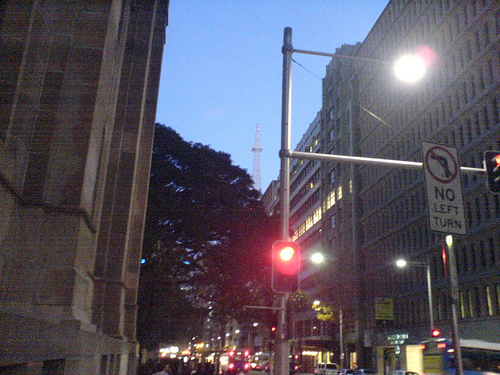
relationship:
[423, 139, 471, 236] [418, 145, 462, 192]
sign with circle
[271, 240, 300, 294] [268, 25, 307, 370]
light on pole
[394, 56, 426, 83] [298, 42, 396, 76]
light on pole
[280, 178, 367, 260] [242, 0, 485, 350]
lights on building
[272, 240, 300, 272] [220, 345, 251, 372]
red light on car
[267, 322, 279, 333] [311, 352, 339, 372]
red light on car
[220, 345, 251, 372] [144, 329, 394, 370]
car on street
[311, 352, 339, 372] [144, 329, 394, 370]
car on street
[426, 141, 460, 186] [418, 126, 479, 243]
circle around arrow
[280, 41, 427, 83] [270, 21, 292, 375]
horizontal pole on pole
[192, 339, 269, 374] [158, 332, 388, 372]
traffic on city street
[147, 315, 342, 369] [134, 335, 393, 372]
lights over street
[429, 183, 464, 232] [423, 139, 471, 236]
words on sign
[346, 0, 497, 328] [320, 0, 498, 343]
face of building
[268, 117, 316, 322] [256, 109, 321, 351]
face of building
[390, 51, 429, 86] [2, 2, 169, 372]
light near building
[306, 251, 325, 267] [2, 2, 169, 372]
light near building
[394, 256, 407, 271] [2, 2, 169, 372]
light near building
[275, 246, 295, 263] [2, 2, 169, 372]
light near building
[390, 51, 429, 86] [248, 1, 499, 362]
light near building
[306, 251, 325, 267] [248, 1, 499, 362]
light near building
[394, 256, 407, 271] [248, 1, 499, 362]
light near building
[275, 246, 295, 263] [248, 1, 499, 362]
light near building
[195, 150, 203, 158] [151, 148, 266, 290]
leaves on tree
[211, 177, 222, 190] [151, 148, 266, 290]
leaves on tree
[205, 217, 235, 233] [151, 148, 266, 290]
leaves on tree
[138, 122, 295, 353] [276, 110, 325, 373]
tree near building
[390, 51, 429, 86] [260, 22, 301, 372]
light on pole